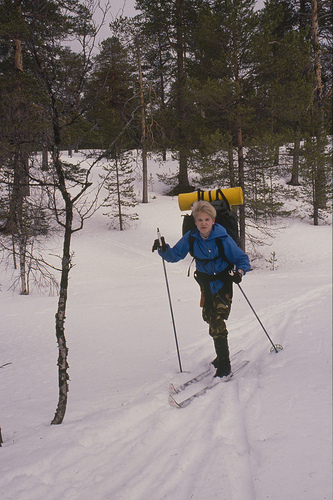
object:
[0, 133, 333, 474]
snow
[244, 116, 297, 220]
tree branches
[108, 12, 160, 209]
tree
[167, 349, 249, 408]
skiis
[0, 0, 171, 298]
branches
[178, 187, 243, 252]
backpack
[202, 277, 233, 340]
pants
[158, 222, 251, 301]
blue sweater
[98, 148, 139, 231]
tree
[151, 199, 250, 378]
person